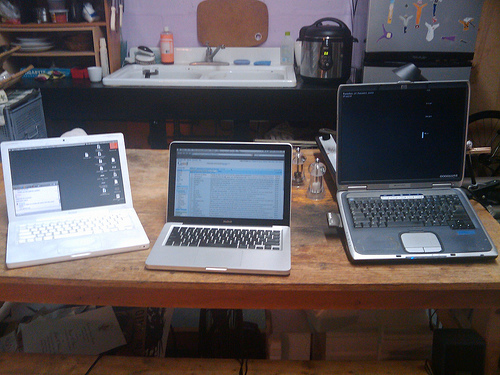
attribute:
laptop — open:
[139, 130, 297, 284]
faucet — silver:
[201, 39, 230, 60]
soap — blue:
[230, 54, 250, 68]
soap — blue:
[250, 55, 277, 67]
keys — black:
[175, 225, 287, 251]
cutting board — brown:
[191, 3, 272, 49]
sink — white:
[108, 43, 297, 95]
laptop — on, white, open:
[5, 129, 154, 264]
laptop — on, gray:
[143, 135, 294, 277]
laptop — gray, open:
[327, 75, 498, 265]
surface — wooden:
[2, 127, 495, 320]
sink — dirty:
[107, 35, 295, 94]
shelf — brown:
[2, 23, 105, 69]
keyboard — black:
[163, 222, 283, 249]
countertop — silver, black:
[14, 113, 490, 293]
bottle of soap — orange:
[148, 16, 188, 65]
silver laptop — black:
[329, 70, 498, 278]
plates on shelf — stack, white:
[5, 30, 60, 55]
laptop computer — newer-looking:
[1, 134, 154, 269]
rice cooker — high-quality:
[286, 13, 358, 83]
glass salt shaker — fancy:
[307, 153, 328, 206]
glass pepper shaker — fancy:
[288, 140, 309, 186]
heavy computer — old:
[322, 69, 497, 269]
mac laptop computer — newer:
[0, 131, 154, 268]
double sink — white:
[104, 40, 299, 93]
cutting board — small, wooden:
[196, 1, 274, 47]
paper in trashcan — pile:
[264, 119, 325, 144]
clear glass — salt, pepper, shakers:
[309, 151, 331, 204]